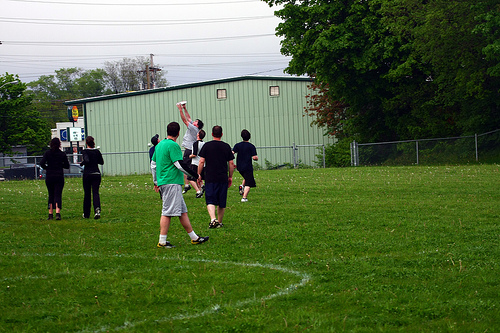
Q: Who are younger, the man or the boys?
A: The boys are younger than the man.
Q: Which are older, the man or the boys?
A: The man are older than the boys.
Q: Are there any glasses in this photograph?
A: No, there are no glasses.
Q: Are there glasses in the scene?
A: No, there are no glasses.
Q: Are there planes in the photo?
A: No, there are no planes.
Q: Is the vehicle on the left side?
A: Yes, the vehicle is on the left of the image.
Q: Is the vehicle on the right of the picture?
A: No, the vehicle is on the left of the image.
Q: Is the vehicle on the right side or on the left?
A: The vehicle is on the left of the image.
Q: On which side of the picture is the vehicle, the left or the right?
A: The vehicle is on the left of the image.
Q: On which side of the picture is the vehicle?
A: The vehicle is on the left of the image.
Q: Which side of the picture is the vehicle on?
A: The vehicle is on the left of the image.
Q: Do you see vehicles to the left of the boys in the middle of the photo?
A: Yes, there is a vehicle to the left of the boys.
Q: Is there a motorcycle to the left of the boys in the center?
A: No, there is a vehicle to the left of the boys.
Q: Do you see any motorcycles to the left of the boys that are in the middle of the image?
A: No, there is a vehicle to the left of the boys.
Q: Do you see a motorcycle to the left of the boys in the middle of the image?
A: No, there is a vehicle to the left of the boys.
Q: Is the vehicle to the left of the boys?
A: Yes, the vehicle is to the left of the boys.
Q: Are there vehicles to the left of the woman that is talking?
A: Yes, there is a vehicle to the left of the woman.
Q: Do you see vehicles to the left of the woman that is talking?
A: Yes, there is a vehicle to the left of the woman.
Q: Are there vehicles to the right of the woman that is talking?
A: No, the vehicle is to the left of the woman.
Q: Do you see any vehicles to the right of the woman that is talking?
A: No, the vehicle is to the left of the woman.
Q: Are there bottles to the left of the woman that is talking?
A: No, there is a vehicle to the left of the woman.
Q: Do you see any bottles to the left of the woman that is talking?
A: No, there is a vehicle to the left of the woman.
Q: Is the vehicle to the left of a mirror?
A: No, the vehicle is to the left of a woman.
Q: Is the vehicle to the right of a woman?
A: No, the vehicle is to the left of a woman.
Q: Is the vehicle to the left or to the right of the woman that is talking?
A: The vehicle is to the left of the woman.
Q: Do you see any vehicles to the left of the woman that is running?
A: Yes, there is a vehicle to the left of the woman.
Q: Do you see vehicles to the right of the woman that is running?
A: No, the vehicle is to the left of the woman.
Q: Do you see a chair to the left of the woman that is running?
A: No, there is a vehicle to the left of the woman.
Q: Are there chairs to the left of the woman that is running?
A: No, there is a vehicle to the left of the woman.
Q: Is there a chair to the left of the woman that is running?
A: No, there is a vehicle to the left of the woman.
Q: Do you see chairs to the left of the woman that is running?
A: No, there is a vehicle to the left of the woman.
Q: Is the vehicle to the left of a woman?
A: Yes, the vehicle is to the left of a woman.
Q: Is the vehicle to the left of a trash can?
A: No, the vehicle is to the left of a woman.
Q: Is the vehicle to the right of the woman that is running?
A: No, the vehicle is to the left of the woman.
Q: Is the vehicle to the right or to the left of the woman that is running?
A: The vehicle is to the left of the woman.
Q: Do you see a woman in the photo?
A: Yes, there is a woman.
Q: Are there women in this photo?
A: Yes, there is a woman.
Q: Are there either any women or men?
A: Yes, there is a woman.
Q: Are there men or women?
A: Yes, there is a woman.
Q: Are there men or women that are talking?
A: Yes, the woman is talking.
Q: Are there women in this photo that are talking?
A: Yes, there is a woman that is talking.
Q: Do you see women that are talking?
A: Yes, there is a woman that is talking.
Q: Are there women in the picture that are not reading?
A: Yes, there is a woman that is talking.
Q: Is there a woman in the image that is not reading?
A: Yes, there is a woman that is talking.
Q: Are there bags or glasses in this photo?
A: No, there are no bags or glasses.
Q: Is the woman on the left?
A: Yes, the woman is on the left of the image.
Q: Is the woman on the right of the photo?
A: No, the woman is on the left of the image.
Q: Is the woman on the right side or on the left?
A: The woman is on the left of the image.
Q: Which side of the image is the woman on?
A: The woman is on the left of the image.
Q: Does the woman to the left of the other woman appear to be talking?
A: Yes, the woman is talking.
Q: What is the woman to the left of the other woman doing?
A: The woman is talking.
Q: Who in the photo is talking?
A: The woman is talking.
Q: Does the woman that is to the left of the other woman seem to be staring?
A: No, the woman is talking.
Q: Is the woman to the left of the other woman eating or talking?
A: The woman is talking.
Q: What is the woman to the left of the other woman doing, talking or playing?
A: The woman is talking.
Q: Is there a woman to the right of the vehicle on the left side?
A: Yes, there is a woman to the right of the vehicle.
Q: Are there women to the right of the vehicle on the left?
A: Yes, there is a woman to the right of the vehicle.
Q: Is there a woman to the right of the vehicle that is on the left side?
A: Yes, there is a woman to the right of the vehicle.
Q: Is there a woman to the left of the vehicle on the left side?
A: No, the woman is to the right of the vehicle.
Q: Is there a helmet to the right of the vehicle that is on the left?
A: No, there is a woman to the right of the vehicle.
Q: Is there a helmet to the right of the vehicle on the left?
A: No, there is a woman to the right of the vehicle.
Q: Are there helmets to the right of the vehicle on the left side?
A: No, there is a woman to the right of the vehicle.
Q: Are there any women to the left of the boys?
A: Yes, there is a woman to the left of the boys.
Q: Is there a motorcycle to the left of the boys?
A: No, there is a woman to the left of the boys.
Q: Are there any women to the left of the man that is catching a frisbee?
A: Yes, there is a woman to the left of the man.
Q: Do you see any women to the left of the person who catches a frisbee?
A: Yes, there is a woman to the left of the man.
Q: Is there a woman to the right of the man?
A: No, the woman is to the left of the man.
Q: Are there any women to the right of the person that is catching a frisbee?
A: No, the woman is to the left of the man.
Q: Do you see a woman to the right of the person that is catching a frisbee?
A: No, the woman is to the left of the man.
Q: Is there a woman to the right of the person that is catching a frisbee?
A: No, the woman is to the left of the man.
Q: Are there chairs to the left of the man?
A: No, there is a woman to the left of the man.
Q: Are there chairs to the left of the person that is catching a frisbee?
A: No, there is a woman to the left of the man.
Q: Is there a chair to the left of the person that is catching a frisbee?
A: No, there is a woman to the left of the man.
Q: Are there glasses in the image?
A: No, there are no glasses.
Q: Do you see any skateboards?
A: No, there are no skateboards.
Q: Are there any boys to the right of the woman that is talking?
A: Yes, there are boys to the right of the woman.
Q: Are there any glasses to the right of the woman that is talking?
A: No, there are boys to the right of the woman.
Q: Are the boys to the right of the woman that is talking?
A: Yes, the boys are to the right of the woman.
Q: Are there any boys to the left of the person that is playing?
A: Yes, there are boys to the left of the person.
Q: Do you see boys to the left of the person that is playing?
A: Yes, there are boys to the left of the person.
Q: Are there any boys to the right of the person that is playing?
A: No, the boys are to the left of the person.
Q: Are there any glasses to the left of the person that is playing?
A: No, there are boys to the left of the person.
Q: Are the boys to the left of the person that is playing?
A: Yes, the boys are to the left of the person.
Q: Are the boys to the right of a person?
A: No, the boys are to the left of a person.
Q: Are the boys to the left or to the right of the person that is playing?
A: The boys are to the left of the person.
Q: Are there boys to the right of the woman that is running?
A: Yes, there are boys to the right of the woman.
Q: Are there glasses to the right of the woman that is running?
A: No, there are boys to the right of the woman.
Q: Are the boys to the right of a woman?
A: Yes, the boys are to the right of a woman.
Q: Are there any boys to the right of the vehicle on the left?
A: Yes, there are boys to the right of the vehicle.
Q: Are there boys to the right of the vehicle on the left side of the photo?
A: Yes, there are boys to the right of the vehicle.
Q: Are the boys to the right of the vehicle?
A: Yes, the boys are to the right of the vehicle.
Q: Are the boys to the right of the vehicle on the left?
A: Yes, the boys are to the right of the vehicle.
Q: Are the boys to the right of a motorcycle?
A: No, the boys are to the right of the vehicle.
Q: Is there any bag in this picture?
A: No, there are no bags.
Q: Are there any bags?
A: No, there are no bags.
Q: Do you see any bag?
A: No, there are no bags.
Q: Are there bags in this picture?
A: No, there are no bags.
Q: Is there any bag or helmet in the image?
A: No, there are no bags or helmets.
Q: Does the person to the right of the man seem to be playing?
A: Yes, the person is playing.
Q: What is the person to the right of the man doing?
A: The person is playing.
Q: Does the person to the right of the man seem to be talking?
A: No, the person is playing.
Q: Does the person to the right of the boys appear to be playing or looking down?
A: The person is playing.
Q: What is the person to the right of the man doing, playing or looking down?
A: The person is playing.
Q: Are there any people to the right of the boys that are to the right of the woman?
A: Yes, there is a person to the right of the boys.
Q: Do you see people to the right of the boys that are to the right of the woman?
A: Yes, there is a person to the right of the boys.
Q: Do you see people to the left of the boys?
A: No, the person is to the right of the boys.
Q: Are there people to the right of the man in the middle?
A: Yes, there is a person to the right of the man.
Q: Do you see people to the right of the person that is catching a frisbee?
A: Yes, there is a person to the right of the man.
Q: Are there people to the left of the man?
A: No, the person is to the right of the man.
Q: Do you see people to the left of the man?
A: No, the person is to the right of the man.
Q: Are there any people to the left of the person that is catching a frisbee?
A: No, the person is to the right of the man.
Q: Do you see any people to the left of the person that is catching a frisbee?
A: No, the person is to the right of the man.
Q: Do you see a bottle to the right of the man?
A: No, there is a person to the right of the man.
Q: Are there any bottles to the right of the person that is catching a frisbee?
A: No, there is a person to the right of the man.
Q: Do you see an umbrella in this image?
A: No, there are no umbrellas.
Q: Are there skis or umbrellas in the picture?
A: No, there are no umbrellas or skis.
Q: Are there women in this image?
A: Yes, there is a woman.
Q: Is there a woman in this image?
A: Yes, there is a woman.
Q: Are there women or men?
A: Yes, there is a woman.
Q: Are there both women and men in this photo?
A: Yes, there are both a woman and a man.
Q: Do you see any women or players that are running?
A: Yes, the woman is running.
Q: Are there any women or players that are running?
A: Yes, the woman is running.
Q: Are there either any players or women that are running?
A: Yes, the woman is running.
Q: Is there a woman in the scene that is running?
A: Yes, there is a woman that is running.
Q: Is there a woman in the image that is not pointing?
A: Yes, there is a woman that is running.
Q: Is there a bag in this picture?
A: No, there are no bags.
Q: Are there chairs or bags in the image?
A: No, there are no bags or chairs.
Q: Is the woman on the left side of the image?
A: Yes, the woman is on the left of the image.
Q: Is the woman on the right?
A: No, the woman is on the left of the image.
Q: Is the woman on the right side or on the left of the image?
A: The woman is on the left of the image.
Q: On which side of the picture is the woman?
A: The woman is on the left of the image.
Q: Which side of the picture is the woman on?
A: The woman is on the left of the image.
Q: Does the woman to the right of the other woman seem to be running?
A: Yes, the woman is running.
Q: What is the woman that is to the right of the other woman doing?
A: The woman is running.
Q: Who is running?
A: The woman is running.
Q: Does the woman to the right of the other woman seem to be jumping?
A: No, the woman is running.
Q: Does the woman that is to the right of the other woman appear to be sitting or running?
A: The woman is running.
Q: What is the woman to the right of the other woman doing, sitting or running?
A: The woman is running.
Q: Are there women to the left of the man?
A: Yes, there is a woman to the left of the man.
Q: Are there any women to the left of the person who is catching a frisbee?
A: Yes, there is a woman to the left of the man.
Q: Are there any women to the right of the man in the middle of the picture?
A: No, the woman is to the left of the man.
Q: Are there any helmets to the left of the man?
A: No, there is a woman to the left of the man.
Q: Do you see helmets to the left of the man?
A: No, there is a woman to the left of the man.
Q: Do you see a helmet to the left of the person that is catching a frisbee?
A: No, there is a woman to the left of the man.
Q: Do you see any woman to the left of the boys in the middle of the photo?
A: Yes, there is a woman to the left of the boys.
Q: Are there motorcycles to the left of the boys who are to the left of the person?
A: No, there is a woman to the left of the boys.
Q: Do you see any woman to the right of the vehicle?
A: Yes, there is a woman to the right of the vehicle.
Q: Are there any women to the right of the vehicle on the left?
A: Yes, there is a woman to the right of the vehicle.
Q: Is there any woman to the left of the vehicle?
A: No, the woman is to the right of the vehicle.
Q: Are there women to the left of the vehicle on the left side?
A: No, the woman is to the right of the vehicle.